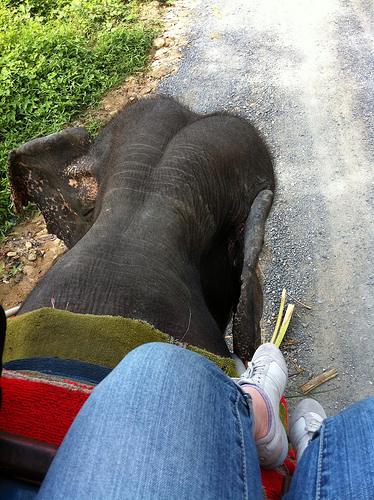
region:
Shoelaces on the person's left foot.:
[244, 353, 264, 382]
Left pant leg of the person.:
[91, 333, 257, 498]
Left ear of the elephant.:
[6, 123, 98, 239]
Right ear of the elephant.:
[236, 180, 269, 348]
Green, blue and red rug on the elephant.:
[1, 306, 218, 473]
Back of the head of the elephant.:
[96, 97, 266, 215]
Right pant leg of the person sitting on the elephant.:
[295, 393, 372, 498]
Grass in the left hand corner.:
[3, 2, 158, 119]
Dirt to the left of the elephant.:
[2, 210, 61, 311]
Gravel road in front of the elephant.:
[186, 2, 370, 428]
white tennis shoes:
[242, 335, 346, 498]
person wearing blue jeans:
[55, 318, 366, 483]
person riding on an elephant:
[6, 85, 372, 489]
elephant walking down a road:
[8, 8, 348, 338]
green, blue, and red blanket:
[7, 292, 224, 468]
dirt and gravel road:
[167, 12, 368, 292]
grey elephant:
[17, 78, 297, 364]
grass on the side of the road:
[1, 27, 318, 255]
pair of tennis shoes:
[238, 326, 330, 469]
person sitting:
[45, 304, 368, 477]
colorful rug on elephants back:
[0, 308, 292, 498]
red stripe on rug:
[0, 376, 89, 447]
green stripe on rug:
[0, 306, 243, 380]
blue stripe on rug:
[0, 358, 110, 388]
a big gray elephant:
[4, 92, 295, 498]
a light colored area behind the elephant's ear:
[68, 172, 101, 199]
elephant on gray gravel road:
[158, 1, 372, 426]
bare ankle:
[238, 383, 272, 438]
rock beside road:
[152, 36, 165, 48]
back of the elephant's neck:
[86, 197, 208, 261]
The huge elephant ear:
[13, 99, 123, 271]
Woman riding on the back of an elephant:
[51, 259, 233, 487]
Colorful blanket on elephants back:
[9, 315, 105, 421]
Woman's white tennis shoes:
[219, 310, 307, 462]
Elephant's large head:
[14, 97, 311, 258]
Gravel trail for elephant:
[105, 5, 319, 93]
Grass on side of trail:
[22, 5, 165, 76]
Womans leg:
[65, 372, 240, 498]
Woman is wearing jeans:
[88, 337, 219, 492]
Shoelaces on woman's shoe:
[233, 362, 262, 381]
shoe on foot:
[233, 341, 290, 470]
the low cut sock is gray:
[241, 382, 275, 432]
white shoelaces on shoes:
[228, 357, 262, 382]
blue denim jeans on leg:
[26, 340, 264, 498]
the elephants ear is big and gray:
[7, 127, 99, 248]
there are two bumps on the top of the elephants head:
[100, 94, 273, 191]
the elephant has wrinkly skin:
[6, 96, 276, 362]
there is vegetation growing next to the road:
[0, 0, 157, 234]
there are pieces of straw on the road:
[270, 287, 296, 345]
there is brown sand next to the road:
[0, 209, 68, 307]